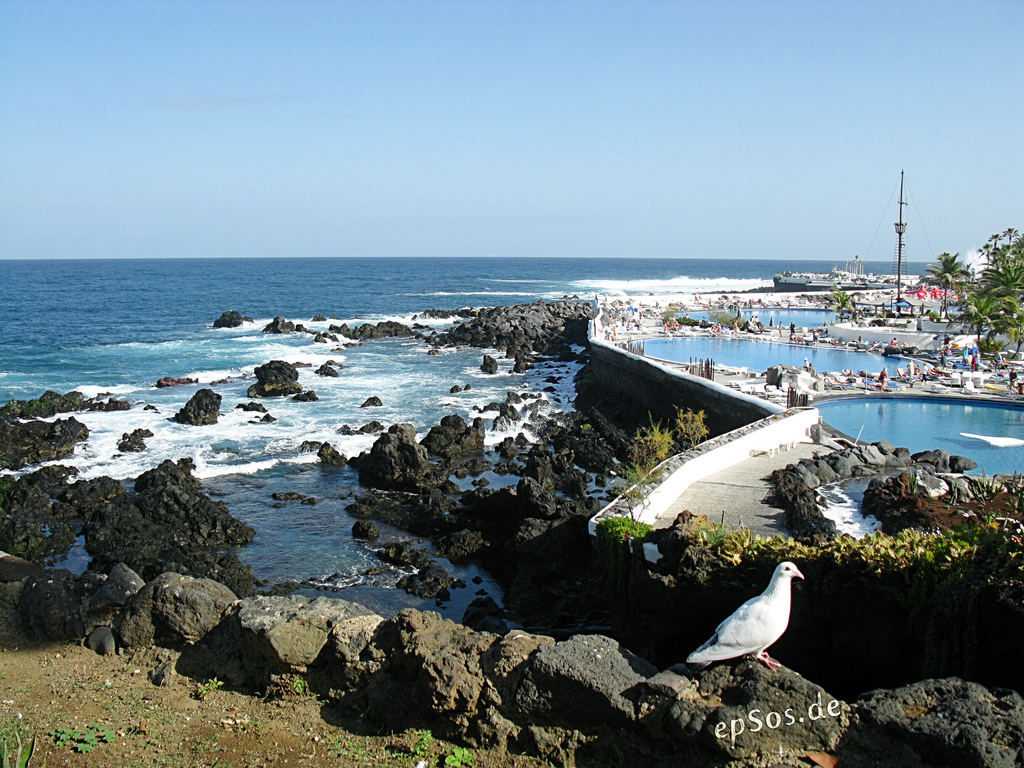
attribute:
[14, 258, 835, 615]
water body — large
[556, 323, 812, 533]
retaining wall — cement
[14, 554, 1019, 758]
retaining wall — rock-lined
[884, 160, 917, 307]
crow's nest — tall, wooden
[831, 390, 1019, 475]
pool — in-ground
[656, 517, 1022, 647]
bush — trimmed, ornamental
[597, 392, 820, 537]
flower planter — white, cement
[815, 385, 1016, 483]
swimming pool — in-ground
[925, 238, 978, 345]
palm tree — ornamental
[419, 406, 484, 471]
rock — big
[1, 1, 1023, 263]
sky — blue, clear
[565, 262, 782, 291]
wave — large, white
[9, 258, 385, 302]
water — calm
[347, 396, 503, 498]
rocks — jagged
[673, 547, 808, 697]
bird — white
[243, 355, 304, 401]
rock — big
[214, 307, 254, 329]
rock — big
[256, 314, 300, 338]
rock — big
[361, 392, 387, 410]
rock — big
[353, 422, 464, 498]
rock — big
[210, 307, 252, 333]
rock — big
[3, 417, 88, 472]
rock — big